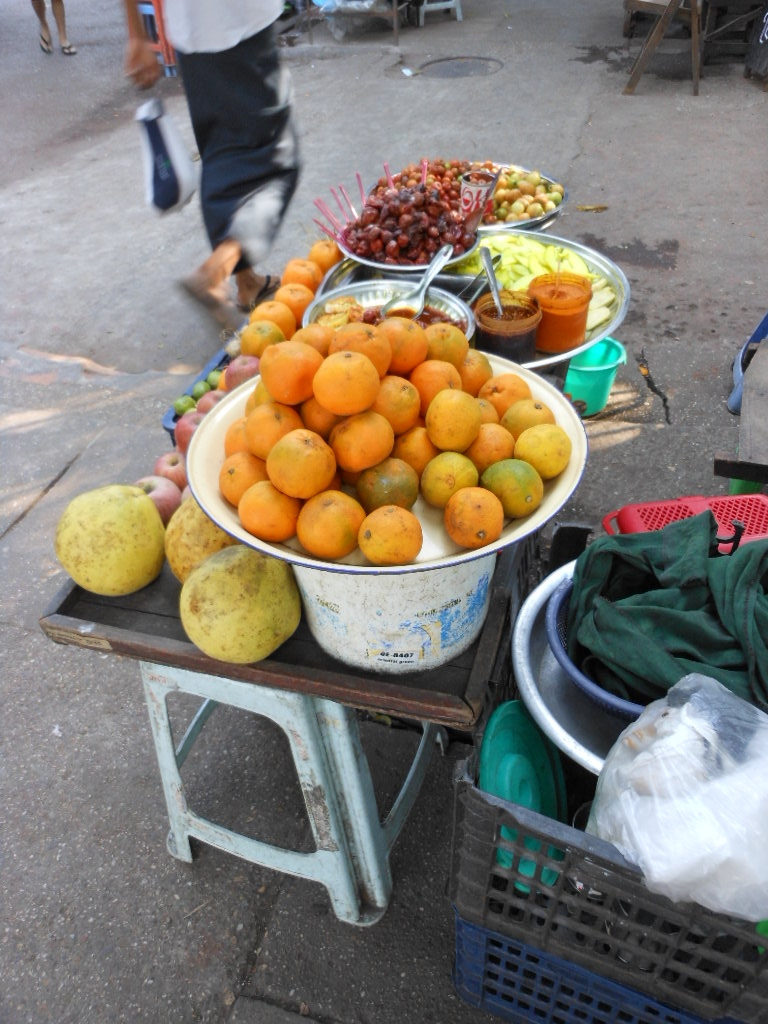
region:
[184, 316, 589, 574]
plate of orange fruit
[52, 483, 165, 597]
rounded yellow fruit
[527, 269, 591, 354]
jar of reddish-orange sauce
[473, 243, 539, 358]
jar of dark red sauce with spoon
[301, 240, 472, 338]
metal dish with a silver spoon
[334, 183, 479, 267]
plate of small red fruits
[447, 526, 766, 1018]
stacked blue and black plastic totes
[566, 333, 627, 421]
teal plastic bucket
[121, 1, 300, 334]
man wearing open sandals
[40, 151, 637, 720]
large display of food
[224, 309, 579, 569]
a pile of oranges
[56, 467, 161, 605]
large yellow fruit on the edge of the table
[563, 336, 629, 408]
green bucket on the ground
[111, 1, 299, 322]
person is walking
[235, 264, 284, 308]
sandal on the foot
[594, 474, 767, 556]
bright red crate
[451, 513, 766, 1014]
a stack of crates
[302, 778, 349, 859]
paint is peeling off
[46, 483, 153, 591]
a large yellow fruit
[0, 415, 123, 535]
crack in the concrete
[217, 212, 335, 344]
a row of oranges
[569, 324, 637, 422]
mint green bucket on the ground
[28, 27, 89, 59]
a pair of sandals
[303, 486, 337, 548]
orange on the plate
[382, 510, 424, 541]
orange on the plate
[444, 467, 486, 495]
orange on the plate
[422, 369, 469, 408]
orange on the plate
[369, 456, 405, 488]
orange on the plate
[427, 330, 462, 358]
orange on the plate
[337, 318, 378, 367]
orange on the plate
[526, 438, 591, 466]
orange on the plate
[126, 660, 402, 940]
a stool that is light blue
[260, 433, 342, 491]
a small orange fruit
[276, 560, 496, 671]
a small white bucket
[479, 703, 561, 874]
a small green lid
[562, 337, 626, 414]
a small green bucket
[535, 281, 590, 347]
a small orange jar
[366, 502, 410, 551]
small orange on the dish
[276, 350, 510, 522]
a lot oranges on a dish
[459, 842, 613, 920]
black basket over other basket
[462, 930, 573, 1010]
blue basket on the pavement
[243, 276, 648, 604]
bunch of oranges on plate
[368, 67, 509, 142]
sidewalk is dark grey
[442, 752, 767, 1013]
grey basket under oranges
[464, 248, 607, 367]
two containers with spread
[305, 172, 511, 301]
red berries on plate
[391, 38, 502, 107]
manhole cover on street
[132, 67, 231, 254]
person is holding bag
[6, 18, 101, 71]
person wears black sandals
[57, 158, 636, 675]
fruit sitting on a bench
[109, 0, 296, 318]
Person walking down the street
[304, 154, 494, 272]
red cherries in a bowl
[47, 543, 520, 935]
fruit bench with white legs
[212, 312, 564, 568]
orange fruit in a white and blue bowl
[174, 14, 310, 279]
blue skirt person is wearing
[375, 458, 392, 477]
an orange on display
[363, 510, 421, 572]
an orange on display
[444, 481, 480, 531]
an orange on display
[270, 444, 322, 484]
an orange on display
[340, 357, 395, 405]
an orange on display